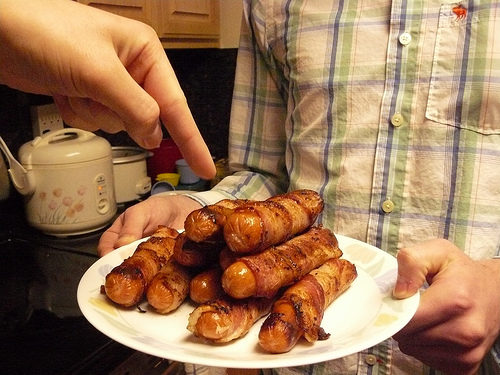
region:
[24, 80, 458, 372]
a plate of food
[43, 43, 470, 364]
someone holding a plate of food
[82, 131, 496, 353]
someone holding a white plate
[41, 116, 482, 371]
someone holding a white plate of food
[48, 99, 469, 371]
bacon covered hotdogs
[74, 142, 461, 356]
a plate of bacon cover hotdogs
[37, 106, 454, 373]
cooked bacon covered hotdogs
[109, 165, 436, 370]
hotdogs covered in bacon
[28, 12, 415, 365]
a finger pointing at the food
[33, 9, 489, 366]
a finger pointing at the plate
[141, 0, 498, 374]
The shirt is white.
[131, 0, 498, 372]
Shirt has a pocket.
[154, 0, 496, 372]
Shirt has horizontal stripes.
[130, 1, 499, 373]
Shirt has vertical stripes.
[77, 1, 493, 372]
Boy is holding plate.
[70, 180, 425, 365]
The plate is round.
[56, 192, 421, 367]
The plate is circular.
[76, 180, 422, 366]
The plate is white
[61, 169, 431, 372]
Hotdog on a plate.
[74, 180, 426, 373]
Hotdogs wrapped in bacon.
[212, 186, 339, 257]
hot dog wrapped in bacon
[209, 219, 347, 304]
hot dog wrapped in bacon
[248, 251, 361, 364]
hot dog wrapped in bacon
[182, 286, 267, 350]
hot dog wrapped in bacon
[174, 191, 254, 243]
hot dog wrapped in bacon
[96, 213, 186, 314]
hot dog wrapped in bacon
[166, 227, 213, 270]
hot dog wrapped in bacon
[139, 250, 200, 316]
hot dog wrapped in bacon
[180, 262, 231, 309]
hot dog wrapped in bacon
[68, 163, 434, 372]
plate of hot dogs wrapped in bacon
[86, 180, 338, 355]
sausage wrapped in bacon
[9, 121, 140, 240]
white flowered crock pot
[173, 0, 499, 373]
man wearing plaid shirt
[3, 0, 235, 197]
white hand with index finger pointing toward sausage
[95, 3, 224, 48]
wooden oak kitchen cabinetry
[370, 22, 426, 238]
white plastic buttons on plaid shirt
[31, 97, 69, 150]
white electrical outlet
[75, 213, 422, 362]
white ceramic plate holding sausage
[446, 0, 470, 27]
small embroidered emblam on plaid shirt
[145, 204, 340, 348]
bacon wrapped hotdogs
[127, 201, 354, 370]
10 bacon wrapped hotdogs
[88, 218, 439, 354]
white plate.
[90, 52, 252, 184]
pointing at the plate.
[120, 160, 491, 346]
two hands holding plate.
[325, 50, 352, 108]
Green and blue stripes.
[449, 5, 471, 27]
orange and yellow emblem.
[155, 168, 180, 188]
yellow measuring cup.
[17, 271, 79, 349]
black counter top.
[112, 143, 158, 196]
White crock pot.